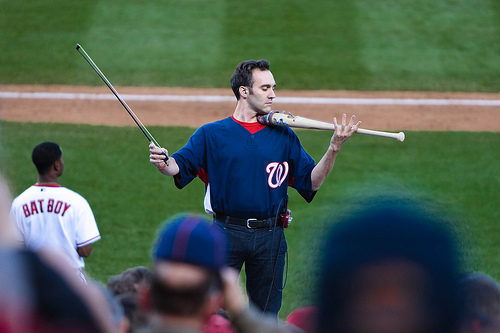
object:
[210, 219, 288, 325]
jeans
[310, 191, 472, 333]
person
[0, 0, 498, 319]
baseball park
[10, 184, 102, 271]
jersey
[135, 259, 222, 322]
head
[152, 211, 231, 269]
blue hat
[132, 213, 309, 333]
man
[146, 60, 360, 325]
man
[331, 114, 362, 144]
hand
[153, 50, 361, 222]
person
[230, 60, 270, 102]
hair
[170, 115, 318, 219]
blue shirt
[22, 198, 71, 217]
batboy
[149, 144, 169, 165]
hand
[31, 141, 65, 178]
head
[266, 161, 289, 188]
w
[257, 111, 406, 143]
baseball bat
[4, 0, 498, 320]
field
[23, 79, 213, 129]
dirt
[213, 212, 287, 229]
belt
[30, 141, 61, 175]
hair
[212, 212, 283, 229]
belt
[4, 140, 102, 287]
boy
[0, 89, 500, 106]
line